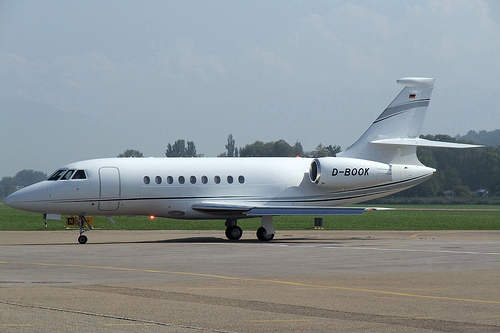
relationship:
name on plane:
[166, 209, 183, 219] [2, 77, 485, 246]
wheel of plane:
[78, 234, 88, 245] [2, 77, 485, 246]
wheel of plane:
[256, 228, 273, 244] [2, 77, 485, 246]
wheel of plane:
[227, 227, 242, 239] [2, 77, 485, 246]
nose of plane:
[5, 178, 47, 217] [2, 77, 485, 246]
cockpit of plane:
[49, 160, 89, 196] [2, 77, 485, 246]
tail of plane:
[337, 78, 484, 167] [2, 77, 485, 246]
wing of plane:
[192, 201, 398, 215] [2, 77, 485, 246]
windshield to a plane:
[50, 168, 66, 179] [2, 77, 485, 246]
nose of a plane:
[5, 178, 47, 217] [2, 77, 485, 246]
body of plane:
[89, 157, 437, 219] [2, 77, 485, 246]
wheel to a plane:
[256, 228, 273, 244] [2, 77, 485, 246]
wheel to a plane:
[227, 227, 242, 239] [2, 77, 485, 246]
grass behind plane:
[275, 206, 498, 231] [2, 77, 485, 246]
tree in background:
[166, 139, 197, 157] [2, 0, 500, 196]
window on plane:
[144, 176, 150, 184] [2, 77, 485, 246]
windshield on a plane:
[50, 168, 66, 179] [2, 77, 485, 246]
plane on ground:
[2, 77, 485, 246] [1, 228, 497, 332]